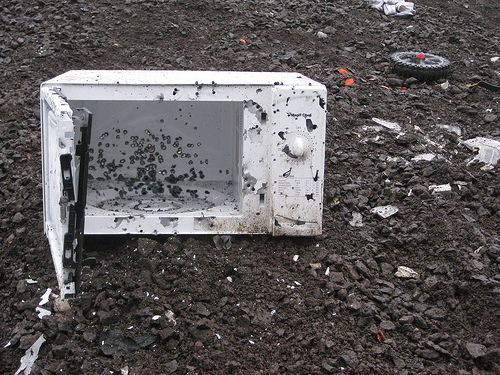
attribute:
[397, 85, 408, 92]
something — red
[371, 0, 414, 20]
cloth — white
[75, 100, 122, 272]
part — black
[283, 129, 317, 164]
knob —  one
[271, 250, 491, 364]
dirt — gravel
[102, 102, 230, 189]
wall — back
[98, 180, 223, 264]
glass —   plate,    microwave's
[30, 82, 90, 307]
door — open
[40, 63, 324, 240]
microwave — white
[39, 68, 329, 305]
microwave — old, white, busted up, dirty 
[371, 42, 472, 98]
wheel — black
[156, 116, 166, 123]
marks — dirty 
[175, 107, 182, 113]
marks — dirty 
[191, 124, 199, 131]
marks — dirty 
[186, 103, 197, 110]
marks — dirty 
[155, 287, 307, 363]
rocks — small 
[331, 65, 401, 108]
pieces — orange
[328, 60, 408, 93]
particles — orange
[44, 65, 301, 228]
microwave — beat up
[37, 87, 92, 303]
door — broken 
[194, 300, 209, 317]
rock — black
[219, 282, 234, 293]
rock — black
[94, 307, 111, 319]
rock — black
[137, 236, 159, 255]
rock — black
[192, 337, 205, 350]
rock — black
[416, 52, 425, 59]
spot — red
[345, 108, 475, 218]
particles — white 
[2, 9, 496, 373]
ground — black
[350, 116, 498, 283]
pieces — broken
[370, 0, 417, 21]
clothes —  some,   dirty,  white